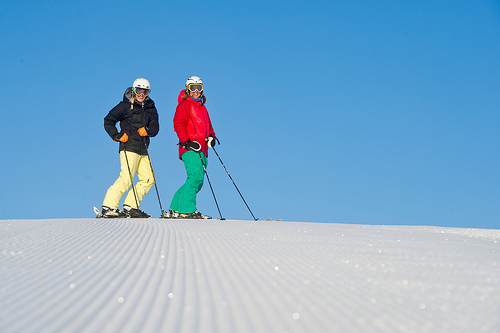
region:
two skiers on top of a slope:
[90, 78, 262, 219]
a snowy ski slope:
[2, 220, 496, 327]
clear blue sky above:
[4, 1, 496, 226]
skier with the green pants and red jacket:
[170, 73, 260, 220]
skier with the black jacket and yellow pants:
[91, 78, 167, 218]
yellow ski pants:
[98, 148, 151, 209]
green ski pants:
[165, 150, 202, 210]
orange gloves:
[120, 125, 145, 140]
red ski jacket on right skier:
[175, 90, 217, 155]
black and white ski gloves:
[184, 136, 214, 151]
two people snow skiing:
[98, 73, 266, 227]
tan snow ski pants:
[102, 146, 154, 211]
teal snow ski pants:
[171, 150, 213, 213]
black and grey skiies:
[85, 200, 157, 220]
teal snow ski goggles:
[128, 85, 156, 97]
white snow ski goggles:
[186, 83, 205, 92]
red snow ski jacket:
[166, 91, 223, 151]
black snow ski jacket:
[102, 91, 164, 154]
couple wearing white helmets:
[128, 72, 208, 98]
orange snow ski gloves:
[136, 124, 151, 138]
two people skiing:
[96, 71, 262, 264]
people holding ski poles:
[117, 125, 241, 211]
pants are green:
[160, 147, 220, 217]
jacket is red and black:
[172, 85, 222, 160]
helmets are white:
[127, 70, 214, 102]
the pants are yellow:
[105, 143, 160, 204]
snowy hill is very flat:
[22, 220, 477, 328]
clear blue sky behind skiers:
[0, 5, 467, 226]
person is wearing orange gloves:
[120, 125, 148, 150]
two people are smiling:
[128, 75, 205, 114]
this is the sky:
[233, 5, 318, 40]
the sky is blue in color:
[293, 29, 363, 72]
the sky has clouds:
[229, 123, 286, 151]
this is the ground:
[135, 227, 240, 298]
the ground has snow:
[82, 228, 232, 285]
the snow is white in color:
[131, 231, 227, 279]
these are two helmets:
[126, 75, 216, 98]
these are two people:
[100, 57, 217, 219]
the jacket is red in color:
[185, 108, 202, 130]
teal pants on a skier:
[177, 150, 205, 218]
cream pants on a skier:
[102, 147, 154, 212]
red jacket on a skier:
[177, 95, 214, 156]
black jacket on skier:
[114, 94, 155, 152]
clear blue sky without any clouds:
[274, 51, 404, 208]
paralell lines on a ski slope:
[95, 251, 216, 331]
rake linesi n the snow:
[117, 240, 214, 304]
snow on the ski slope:
[151, 241, 275, 331]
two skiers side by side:
[82, 31, 287, 251]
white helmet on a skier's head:
[124, 80, 158, 107]